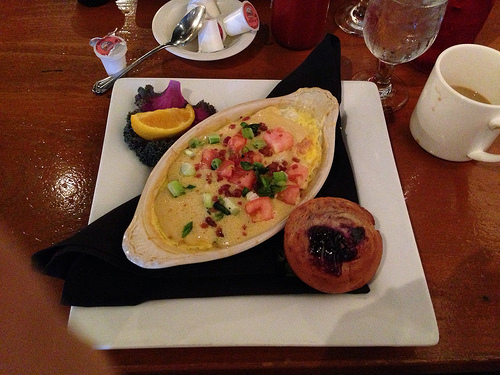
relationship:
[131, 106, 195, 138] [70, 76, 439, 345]
orange on a plate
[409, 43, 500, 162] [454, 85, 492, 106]
coffee cup with coffee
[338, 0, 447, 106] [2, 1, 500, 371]
glass on table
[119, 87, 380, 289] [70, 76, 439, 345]
meal on a plate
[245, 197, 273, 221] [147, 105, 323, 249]
tomato on top of food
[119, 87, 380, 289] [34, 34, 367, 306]
meal on black napkin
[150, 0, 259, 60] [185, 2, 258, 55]
bowl with creamer packets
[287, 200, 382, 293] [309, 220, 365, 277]
pastry with jam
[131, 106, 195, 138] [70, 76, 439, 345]
orange next to plate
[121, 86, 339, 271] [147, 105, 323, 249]
dish with food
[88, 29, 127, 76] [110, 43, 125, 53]
packet of creamer with milk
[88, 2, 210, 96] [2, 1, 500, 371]
napkin on table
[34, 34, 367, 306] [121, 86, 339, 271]
napkin under dish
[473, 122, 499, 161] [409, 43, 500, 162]
handle of coffee cup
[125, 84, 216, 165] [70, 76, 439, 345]
garnish on plate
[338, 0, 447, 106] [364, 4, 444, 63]
glass with water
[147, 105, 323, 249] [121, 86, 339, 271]
food in a dish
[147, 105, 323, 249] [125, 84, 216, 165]
food with garnish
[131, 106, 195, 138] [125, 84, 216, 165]
orange on  top of garnish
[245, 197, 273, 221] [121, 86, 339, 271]
tomato on top of dish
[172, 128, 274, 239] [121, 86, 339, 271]
green onions in dish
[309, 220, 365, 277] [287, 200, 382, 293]
jam on top of pastry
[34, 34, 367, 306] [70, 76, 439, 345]
napkin on top of plate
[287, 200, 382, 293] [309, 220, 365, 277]
pastry filled with jam